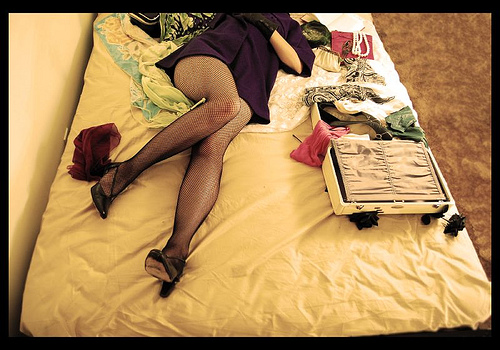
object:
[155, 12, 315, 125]
coat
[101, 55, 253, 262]
fishnets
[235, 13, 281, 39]
glove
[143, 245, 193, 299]
heels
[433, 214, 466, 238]
flower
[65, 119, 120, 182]
object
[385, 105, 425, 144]
item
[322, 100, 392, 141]
skirt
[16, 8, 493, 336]
bed sheet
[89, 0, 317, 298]
girl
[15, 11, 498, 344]
bed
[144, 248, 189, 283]
foot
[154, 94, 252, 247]
legs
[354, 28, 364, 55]
sipper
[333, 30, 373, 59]
scarf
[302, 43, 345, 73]
makeup bag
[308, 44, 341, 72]
closure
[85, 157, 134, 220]
shoe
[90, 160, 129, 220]
feet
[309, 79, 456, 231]
luggage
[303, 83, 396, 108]
clothes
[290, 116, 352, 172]
clothes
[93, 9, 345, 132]
blanket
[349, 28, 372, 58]
necklace